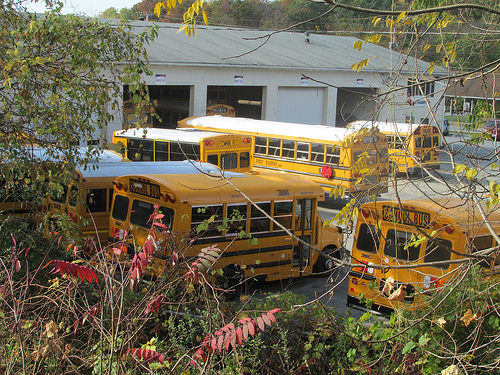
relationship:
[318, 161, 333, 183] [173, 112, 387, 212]
sign on bus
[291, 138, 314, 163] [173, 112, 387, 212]
window on bus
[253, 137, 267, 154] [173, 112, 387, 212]
window on bus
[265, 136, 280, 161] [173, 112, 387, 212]
window on bus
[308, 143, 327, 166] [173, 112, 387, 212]
window on bus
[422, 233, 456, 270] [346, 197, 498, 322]
window on bus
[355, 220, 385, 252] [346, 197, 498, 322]
window on bus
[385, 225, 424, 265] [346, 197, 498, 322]
window on bus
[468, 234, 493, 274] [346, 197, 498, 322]
window on bus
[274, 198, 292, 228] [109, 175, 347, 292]
window on bus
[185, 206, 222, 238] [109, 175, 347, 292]
window on bus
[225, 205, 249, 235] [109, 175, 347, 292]
window on bus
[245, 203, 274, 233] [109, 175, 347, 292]
window on bus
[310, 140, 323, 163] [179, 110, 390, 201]
window on bus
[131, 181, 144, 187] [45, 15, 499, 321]
stripe on school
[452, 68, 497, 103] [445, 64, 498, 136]
roof on house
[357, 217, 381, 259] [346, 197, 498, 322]
bus window on bus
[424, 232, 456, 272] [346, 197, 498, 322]
bus window on bus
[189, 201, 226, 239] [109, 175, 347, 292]
bus window on bus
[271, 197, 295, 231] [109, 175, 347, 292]
bus window on bus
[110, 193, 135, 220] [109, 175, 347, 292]
bus window on bus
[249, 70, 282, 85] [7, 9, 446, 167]
wall on side of a building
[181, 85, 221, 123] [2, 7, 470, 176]
wall on building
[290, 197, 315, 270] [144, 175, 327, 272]
door on bus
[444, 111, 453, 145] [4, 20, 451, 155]
car behind building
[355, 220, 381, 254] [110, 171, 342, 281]
window of a bus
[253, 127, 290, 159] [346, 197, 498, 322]
window on bus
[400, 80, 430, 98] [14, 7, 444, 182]
window on building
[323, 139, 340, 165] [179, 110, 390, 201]
window on bus